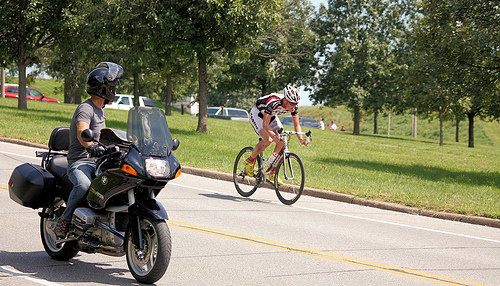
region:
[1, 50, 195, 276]
a motorcycle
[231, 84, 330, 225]
a bicycle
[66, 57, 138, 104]
a motorcycle helmet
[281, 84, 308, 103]
a biker helmet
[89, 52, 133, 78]
a visor on a motorcycle helmet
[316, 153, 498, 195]
a shadow in the grass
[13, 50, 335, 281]
two people riding different types of bikes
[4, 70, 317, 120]
suv vehicles in the background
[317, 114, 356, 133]
three people in the background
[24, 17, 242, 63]
trees with green leaves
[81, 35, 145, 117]
Black helmet on head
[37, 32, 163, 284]
Man on motorcycle on road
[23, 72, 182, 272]
Motorcycle is black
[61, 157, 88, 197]
Man wearing blue jeans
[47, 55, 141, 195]
Man wearing gray shirt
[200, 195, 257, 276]
Yellow lines on the road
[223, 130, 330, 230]
Man on bike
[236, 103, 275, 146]
Man wearing white shorts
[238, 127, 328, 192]
Two black tires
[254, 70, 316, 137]
White helmet on man's head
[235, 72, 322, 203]
Man riding bike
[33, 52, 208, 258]
Black motorcycle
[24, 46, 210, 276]
Man riding a motorcycle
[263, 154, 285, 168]
Water bottle on a bike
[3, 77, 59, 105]
Red car parked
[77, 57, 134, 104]
Black Motorcycle helment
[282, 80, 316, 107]
Red white and black bike helmet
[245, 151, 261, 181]
Biker in yellow shoes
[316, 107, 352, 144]
People standing near a car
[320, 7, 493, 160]
Big trees in a field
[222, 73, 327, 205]
cyclist on side of road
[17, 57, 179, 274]
man on motorcycle looking at cyclist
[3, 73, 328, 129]
row of cars parked along street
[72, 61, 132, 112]
man wearing a black motorcycle helmet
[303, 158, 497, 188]
shadow cast by tree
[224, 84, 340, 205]
cyclist in white, red and black cycling outfit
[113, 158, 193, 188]
orange blinkers on motorcycle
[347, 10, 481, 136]
tall green leafy trees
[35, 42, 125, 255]
man on motorcycle wearing jeans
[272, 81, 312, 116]
man wearing white cycling helmet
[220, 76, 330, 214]
Man riding bicycle down street.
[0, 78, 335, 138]
Four vehicles parked along sidewalk.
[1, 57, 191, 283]
Man sitting on a motorcycle in the street.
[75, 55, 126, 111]
Black helmet with the visor pulled up.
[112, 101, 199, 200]
Shield and headlight on front of motorcycle.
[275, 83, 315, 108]
Cyclists helmet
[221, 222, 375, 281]
Double yellow line running down middle of street.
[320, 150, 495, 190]
Shadow on grass.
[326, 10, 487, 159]
Trees in a grassy field.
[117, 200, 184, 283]
Motorcycle tire.